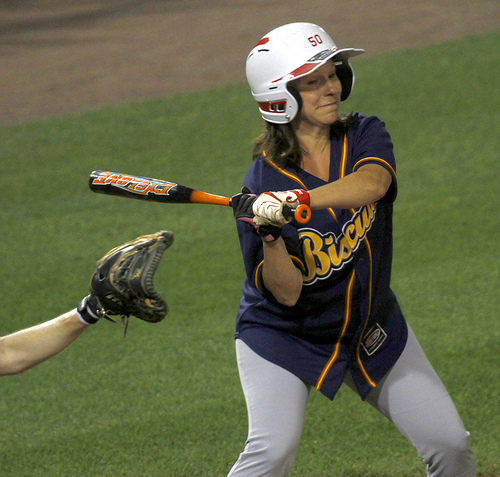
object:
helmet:
[243, 20, 365, 126]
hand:
[78, 228, 172, 324]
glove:
[249, 186, 309, 227]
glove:
[229, 186, 283, 245]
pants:
[227, 320, 476, 476]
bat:
[85, 169, 313, 225]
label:
[357, 319, 389, 357]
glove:
[83, 229, 175, 335]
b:
[295, 226, 333, 289]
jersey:
[233, 114, 409, 402]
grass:
[0, 31, 498, 476]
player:
[221, 22, 479, 476]